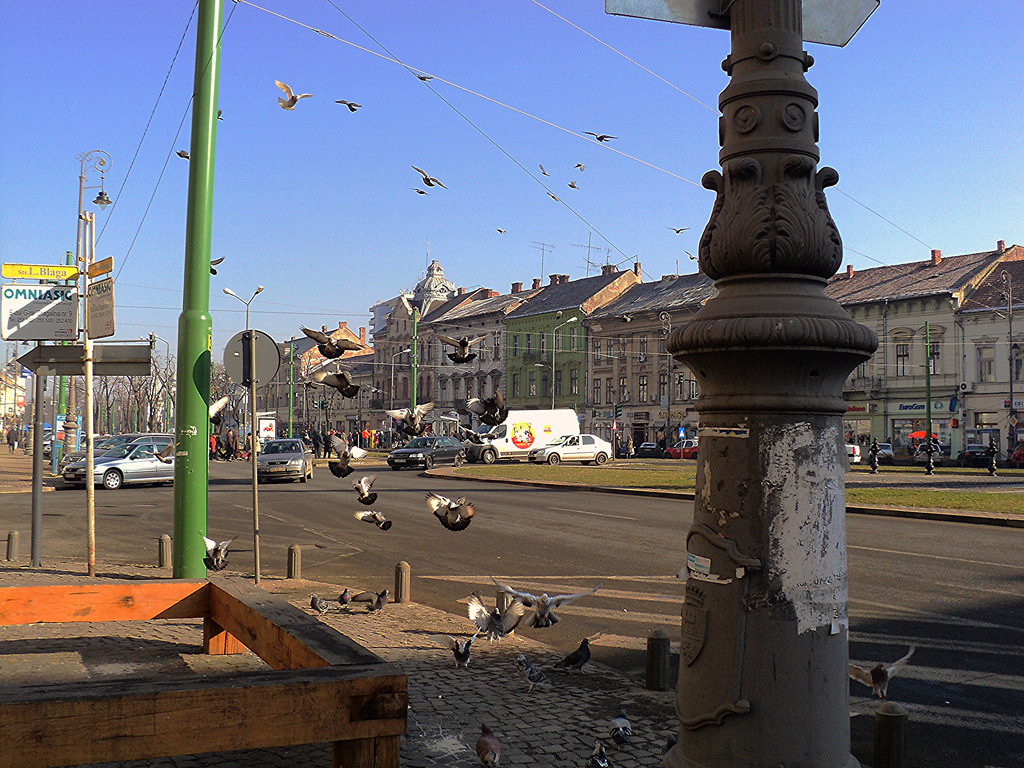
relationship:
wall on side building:
[948, 370, 1000, 442] [15, 242, 1024, 465]